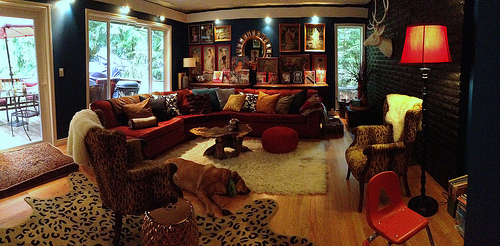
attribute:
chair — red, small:
[359, 172, 436, 245]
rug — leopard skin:
[9, 181, 315, 245]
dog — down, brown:
[159, 152, 257, 218]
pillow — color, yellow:
[120, 99, 157, 119]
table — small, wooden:
[186, 116, 255, 162]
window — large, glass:
[87, 22, 171, 94]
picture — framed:
[278, 23, 299, 54]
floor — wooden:
[282, 197, 362, 241]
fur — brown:
[172, 160, 205, 178]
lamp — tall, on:
[402, 24, 456, 218]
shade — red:
[397, 26, 455, 66]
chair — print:
[66, 106, 182, 244]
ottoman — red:
[259, 126, 301, 152]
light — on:
[157, 12, 167, 24]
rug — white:
[252, 153, 328, 197]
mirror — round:
[238, 31, 274, 62]